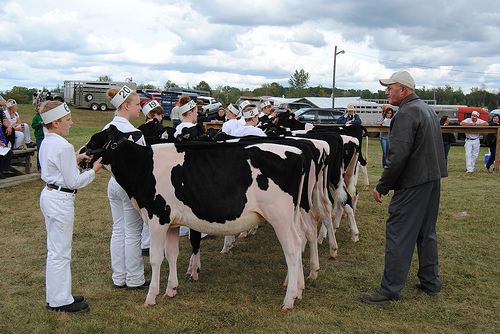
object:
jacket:
[389, 101, 446, 185]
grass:
[106, 298, 490, 328]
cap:
[385, 70, 417, 88]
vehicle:
[64, 81, 151, 111]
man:
[374, 69, 438, 300]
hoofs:
[144, 287, 157, 307]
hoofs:
[281, 298, 295, 308]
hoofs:
[309, 267, 322, 278]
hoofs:
[190, 270, 200, 280]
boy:
[37, 100, 96, 317]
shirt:
[38, 137, 86, 192]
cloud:
[1, 2, 498, 94]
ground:
[0, 130, 500, 334]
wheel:
[84, 95, 94, 103]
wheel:
[92, 104, 97, 111]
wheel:
[99, 102, 107, 111]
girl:
[110, 84, 147, 288]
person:
[0, 127, 5, 175]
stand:
[0, 144, 37, 177]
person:
[3, 100, 33, 151]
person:
[0, 96, 8, 140]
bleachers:
[2, 117, 37, 186]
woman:
[382, 106, 391, 161]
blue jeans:
[381, 135, 389, 167]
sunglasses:
[384, 111, 390, 115]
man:
[458, 109, 488, 176]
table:
[366, 125, 500, 136]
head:
[72, 126, 132, 172]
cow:
[85, 138, 306, 300]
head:
[106, 84, 144, 119]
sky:
[1, 3, 498, 81]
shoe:
[53, 303, 88, 311]